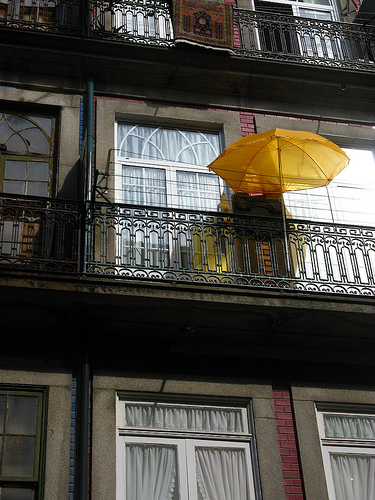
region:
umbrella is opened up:
[119, 101, 371, 279]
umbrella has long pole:
[202, 102, 345, 280]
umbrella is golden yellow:
[201, 100, 346, 195]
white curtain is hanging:
[95, 92, 239, 288]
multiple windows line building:
[11, 11, 373, 484]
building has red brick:
[234, 361, 334, 495]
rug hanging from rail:
[162, 3, 266, 66]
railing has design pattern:
[67, 176, 373, 319]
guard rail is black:
[79, 177, 366, 297]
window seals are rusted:
[4, 79, 65, 234]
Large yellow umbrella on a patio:
[206, 127, 351, 270]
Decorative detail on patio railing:
[0, 191, 372, 299]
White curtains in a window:
[114, 389, 258, 498]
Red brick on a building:
[269, 388, 308, 496]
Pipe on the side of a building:
[77, 77, 103, 279]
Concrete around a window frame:
[91, 374, 285, 497]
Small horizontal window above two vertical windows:
[114, 396, 254, 497]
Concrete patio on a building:
[82, 197, 370, 351]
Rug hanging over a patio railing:
[167, 1, 242, 57]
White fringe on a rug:
[170, 1, 234, 54]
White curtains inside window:
[114, 400, 255, 498]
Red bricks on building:
[267, 382, 320, 498]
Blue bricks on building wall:
[66, 371, 76, 495]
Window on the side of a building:
[107, 111, 239, 272]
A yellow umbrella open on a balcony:
[208, 128, 355, 273]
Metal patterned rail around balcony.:
[0, 191, 373, 298]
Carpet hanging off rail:
[173, 0, 233, 53]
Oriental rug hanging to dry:
[173, 0, 239, 55]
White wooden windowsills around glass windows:
[115, 398, 252, 498]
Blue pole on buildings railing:
[85, 80, 95, 214]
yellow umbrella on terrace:
[208, 117, 355, 189]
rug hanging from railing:
[167, 2, 239, 51]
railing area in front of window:
[87, 201, 315, 285]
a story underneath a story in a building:
[6, 350, 374, 497]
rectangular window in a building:
[115, 404, 250, 432]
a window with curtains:
[114, 127, 223, 262]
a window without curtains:
[2, 113, 53, 246]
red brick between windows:
[282, 392, 300, 496]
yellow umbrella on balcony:
[216, 121, 357, 250]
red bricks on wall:
[255, 388, 311, 498]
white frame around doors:
[118, 404, 276, 497]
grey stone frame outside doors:
[89, 375, 284, 494]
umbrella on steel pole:
[271, 150, 317, 268]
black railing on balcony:
[102, 197, 373, 297]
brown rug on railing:
[162, 0, 234, 55]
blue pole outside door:
[60, 118, 116, 190]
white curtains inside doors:
[123, 411, 242, 496]